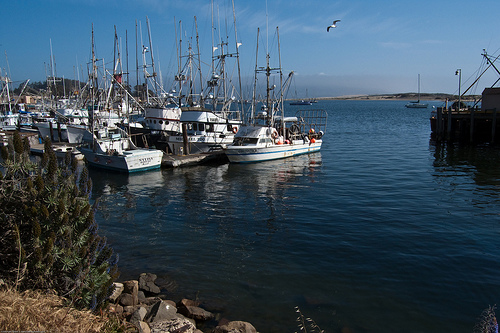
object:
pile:
[93, 268, 254, 333]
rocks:
[102, 268, 255, 331]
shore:
[0, 147, 287, 330]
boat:
[70, 25, 166, 175]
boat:
[30, 38, 122, 144]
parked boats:
[0, 5, 327, 173]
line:
[164, 299, 172, 311]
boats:
[0, 39, 66, 146]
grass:
[0, 286, 103, 333]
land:
[337, 92, 480, 101]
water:
[16, 98, 499, 331]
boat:
[222, 26, 328, 163]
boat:
[289, 93, 312, 106]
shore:
[398, 74, 485, 181]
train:
[6, 135, 84, 160]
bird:
[327, 20, 341, 33]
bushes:
[0, 134, 130, 307]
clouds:
[313, 39, 360, 74]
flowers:
[58, 188, 73, 209]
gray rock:
[176, 297, 223, 322]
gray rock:
[137, 271, 180, 293]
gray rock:
[213, 320, 259, 332]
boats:
[405, 73, 429, 107]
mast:
[248, 0, 294, 138]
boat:
[169, 0, 244, 158]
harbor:
[15, 93, 498, 309]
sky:
[282, 45, 473, 92]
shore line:
[85, 237, 296, 327]